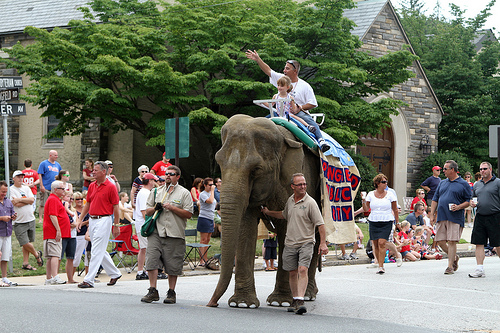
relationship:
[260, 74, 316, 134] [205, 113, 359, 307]
child on top of elephant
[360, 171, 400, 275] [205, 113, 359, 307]
woman behind elephant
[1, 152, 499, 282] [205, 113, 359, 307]
people are watching elephant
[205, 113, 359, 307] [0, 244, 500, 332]
elephant on top of road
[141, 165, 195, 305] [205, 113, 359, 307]
trainer next to elephant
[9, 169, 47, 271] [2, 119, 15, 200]
man leaning on pole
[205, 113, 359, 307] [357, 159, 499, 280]
elephant in front of people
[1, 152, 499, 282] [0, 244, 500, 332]
people are gathered in street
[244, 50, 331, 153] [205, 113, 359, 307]
guy on top of elephant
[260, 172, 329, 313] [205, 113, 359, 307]
person guiding elephant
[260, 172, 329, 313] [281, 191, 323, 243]
person wearing shirt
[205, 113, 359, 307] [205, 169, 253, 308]
elephant has a trunk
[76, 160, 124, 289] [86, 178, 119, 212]
guy has red shirt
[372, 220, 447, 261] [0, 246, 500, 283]
kids are sitting down on curb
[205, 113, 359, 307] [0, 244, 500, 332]
elephant walking on road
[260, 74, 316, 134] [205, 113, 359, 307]
girl riding elephant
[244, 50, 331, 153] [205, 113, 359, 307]
man on top of elephant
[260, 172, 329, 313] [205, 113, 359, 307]
man holding elephant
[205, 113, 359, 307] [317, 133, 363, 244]
elephant has sign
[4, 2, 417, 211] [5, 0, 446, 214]
tree in front of building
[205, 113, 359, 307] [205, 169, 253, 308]
elephant has trunk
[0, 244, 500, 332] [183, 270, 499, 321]
road has line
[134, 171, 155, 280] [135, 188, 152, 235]
man wearing top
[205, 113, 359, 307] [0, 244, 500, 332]
elephant on top of street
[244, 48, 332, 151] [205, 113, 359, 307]
two people sitting on top of elephant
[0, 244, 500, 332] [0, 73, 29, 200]
street has sign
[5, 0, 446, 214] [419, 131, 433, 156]
building has a light